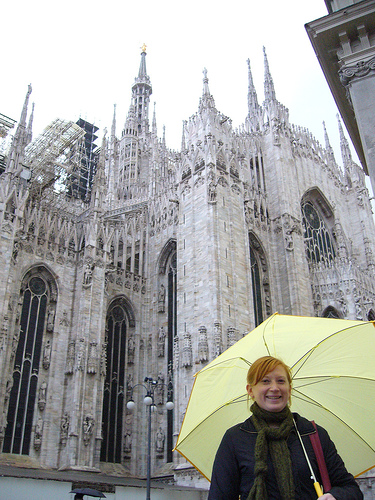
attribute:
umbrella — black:
[65, 485, 106, 498]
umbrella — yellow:
[188, 295, 374, 427]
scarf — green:
[233, 403, 345, 498]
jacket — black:
[221, 425, 362, 472]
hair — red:
[249, 356, 275, 373]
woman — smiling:
[206, 356, 366, 497]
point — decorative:
[200, 68, 215, 109]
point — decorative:
[246, 55, 258, 110]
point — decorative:
[263, 46, 275, 102]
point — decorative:
[133, 41, 149, 132]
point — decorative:
[151, 100, 157, 131]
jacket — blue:
[206, 415, 362, 498]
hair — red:
[246, 355, 292, 395]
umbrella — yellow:
[171, 310, 373, 479]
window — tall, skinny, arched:
[0, 258, 63, 459]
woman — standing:
[204, 346, 370, 496]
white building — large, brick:
[6, 71, 371, 497]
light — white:
[144, 396, 157, 405]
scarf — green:
[247, 403, 298, 498]